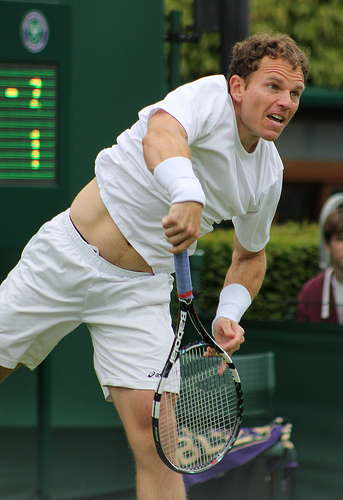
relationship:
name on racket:
[172, 303, 187, 368] [151, 244, 245, 476]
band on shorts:
[65, 218, 115, 275] [0, 210, 175, 400]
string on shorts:
[84, 233, 102, 258] [0, 210, 175, 400]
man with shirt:
[0, 30, 310, 499] [107, 98, 288, 248]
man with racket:
[0, 30, 310, 499] [166, 241, 240, 478]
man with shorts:
[0, 30, 310, 499] [0, 222, 175, 386]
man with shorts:
[0, 30, 310, 499] [0, 251, 191, 396]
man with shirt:
[0, 30, 310, 499] [94, 72, 285, 270]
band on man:
[217, 281, 244, 325] [0, 30, 310, 499]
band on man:
[156, 163, 204, 202] [0, 30, 310, 499]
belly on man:
[84, 204, 147, 275] [0, 30, 310, 499]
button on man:
[119, 241, 134, 250] [0, 30, 310, 499]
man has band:
[0, 30, 310, 499] [219, 280, 245, 321]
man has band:
[0, 30, 310, 499] [150, 163, 204, 203]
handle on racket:
[173, 245, 192, 304] [147, 249, 257, 477]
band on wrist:
[211, 283, 251, 339] [157, 164, 204, 205]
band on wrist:
[153, 156, 206, 207] [223, 284, 246, 323]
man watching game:
[294, 192, 343, 326] [5, 37, 321, 430]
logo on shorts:
[144, 363, 172, 383] [0, 222, 175, 386]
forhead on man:
[253, 52, 304, 83] [0, 30, 310, 499]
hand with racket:
[162, 186, 203, 259] [147, 248, 246, 476]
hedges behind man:
[212, 223, 311, 283] [294, 192, 343, 326]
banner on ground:
[172, 428, 297, 452] [212, 448, 324, 497]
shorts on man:
[0, 222, 175, 386] [0, 30, 310, 499]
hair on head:
[244, 42, 303, 64] [231, 32, 303, 138]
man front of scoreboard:
[0, 30, 310, 499] [5, 70, 54, 182]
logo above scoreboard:
[22, 13, 47, 50] [4, 65, 57, 182]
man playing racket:
[110, 29, 332, 262] [151, 244, 245, 476]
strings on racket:
[157, 357, 293, 479] [156, 226, 287, 491]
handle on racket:
[149, 205, 221, 316] [144, 216, 298, 478]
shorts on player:
[0, 208, 182, 403] [20, 2, 297, 404]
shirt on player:
[96, 36, 310, 311] [17, 14, 255, 347]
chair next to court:
[165, 317, 294, 481] [6, 397, 332, 492]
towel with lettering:
[177, 406, 319, 497] [179, 419, 324, 453]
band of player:
[211, 283, 251, 339] [31, 24, 327, 422]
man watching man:
[294, 181, 332, 256] [0, 30, 310, 499]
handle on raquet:
[173, 245, 192, 304] [144, 235, 245, 463]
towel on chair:
[238, 416, 286, 455] [184, 342, 314, 481]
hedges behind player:
[192, 7, 332, 63] [73, 62, 309, 394]